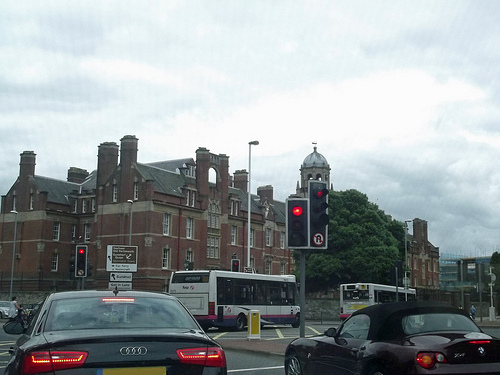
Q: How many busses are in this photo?
A: Two.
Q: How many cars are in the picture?
A: Two.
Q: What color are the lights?
A: Red.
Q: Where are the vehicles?
A: On a road way.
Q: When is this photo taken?
A: During daylight hours.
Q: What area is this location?
A: Town or city.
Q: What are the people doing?
A: Waiting for the light to change.